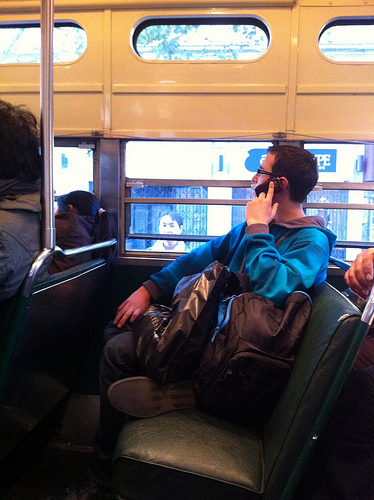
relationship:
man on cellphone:
[150, 144, 334, 349] [256, 174, 282, 193]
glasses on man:
[255, 167, 282, 178] [77, 145, 337, 500]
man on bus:
[143, 211, 189, 253] [0, 0, 373, 499]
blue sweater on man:
[145, 217, 336, 294] [85, 143, 337, 462]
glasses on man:
[257, 167, 282, 177] [136, 132, 336, 340]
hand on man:
[114, 284, 147, 327] [77, 145, 337, 500]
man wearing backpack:
[77, 145, 337, 500] [189, 272, 312, 427]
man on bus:
[77, 145, 337, 500] [0, 0, 373, 499]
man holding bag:
[77, 145, 337, 500] [131, 259, 237, 384]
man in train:
[143, 211, 189, 253] [2, 0, 373, 496]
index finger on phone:
[265, 179, 276, 197] [250, 174, 284, 201]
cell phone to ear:
[255, 178, 284, 198] [278, 176, 287, 190]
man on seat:
[77, 145, 337, 500] [108, 283, 363, 497]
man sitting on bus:
[77, 145, 337, 500] [0, 0, 373, 499]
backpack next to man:
[191, 287, 312, 427] [54, 140, 338, 463]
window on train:
[135, 23, 268, 59] [2, 0, 373, 496]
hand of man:
[240, 179, 281, 223] [77, 145, 337, 500]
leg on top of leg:
[67, 326, 148, 490] [106, 322, 195, 420]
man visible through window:
[143, 211, 189, 253] [120, 131, 298, 261]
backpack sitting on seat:
[191, 287, 312, 427] [65, 281, 342, 498]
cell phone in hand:
[255, 178, 284, 198] [245, 181, 279, 228]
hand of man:
[245, 181, 279, 228] [77, 145, 337, 500]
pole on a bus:
[30, 10, 77, 252] [0, 0, 373, 499]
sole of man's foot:
[106, 377, 197, 419] [105, 372, 201, 414]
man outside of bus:
[143, 211, 189, 253] [0, 0, 373, 499]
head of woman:
[56, 189, 116, 269] [41, 191, 119, 273]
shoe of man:
[106, 376, 198, 419] [77, 145, 337, 500]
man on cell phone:
[77, 145, 337, 500] [253, 181, 274, 227]